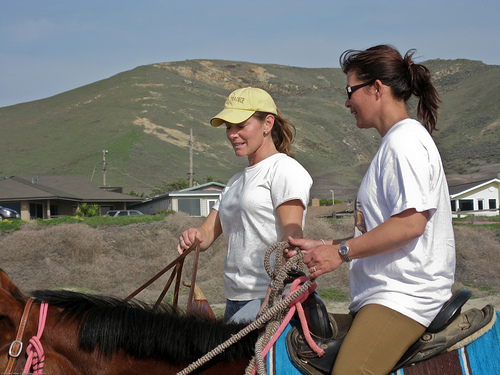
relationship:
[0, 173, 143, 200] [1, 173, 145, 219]
roof of house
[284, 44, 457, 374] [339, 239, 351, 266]
woman wearing watch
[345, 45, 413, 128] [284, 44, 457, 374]
head of woman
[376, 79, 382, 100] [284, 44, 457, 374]
ear of woman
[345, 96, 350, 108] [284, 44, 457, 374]
nose of woman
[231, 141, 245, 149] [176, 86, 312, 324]
mouth of woman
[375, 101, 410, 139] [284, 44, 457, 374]
neck of woman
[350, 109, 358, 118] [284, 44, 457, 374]
lips of woman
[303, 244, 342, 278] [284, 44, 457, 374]
hand of woman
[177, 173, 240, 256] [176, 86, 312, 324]
arm of woman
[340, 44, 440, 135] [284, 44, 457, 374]
hair of woman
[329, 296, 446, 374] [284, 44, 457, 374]
leg of woman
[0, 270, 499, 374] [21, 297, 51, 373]
horse wearing halter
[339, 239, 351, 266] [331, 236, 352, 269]
watch on wrist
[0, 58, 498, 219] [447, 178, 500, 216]
hills surrounding home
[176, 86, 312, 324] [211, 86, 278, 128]
woman wearing cap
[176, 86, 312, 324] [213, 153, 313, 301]
woman wearing shirt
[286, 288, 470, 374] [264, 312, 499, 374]
saddle on blanket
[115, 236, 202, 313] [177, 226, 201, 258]
rein in hand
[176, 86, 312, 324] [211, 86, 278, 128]
woman in hat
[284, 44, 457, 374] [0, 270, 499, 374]
woman on horse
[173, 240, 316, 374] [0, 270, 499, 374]
rope on horse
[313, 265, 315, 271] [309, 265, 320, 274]
ring on finger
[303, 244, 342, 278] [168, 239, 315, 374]
hand holding rein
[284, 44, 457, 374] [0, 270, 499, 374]
lady riding horse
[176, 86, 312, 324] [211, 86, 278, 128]
lady wearing hat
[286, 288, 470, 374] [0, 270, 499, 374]
saddle on horse